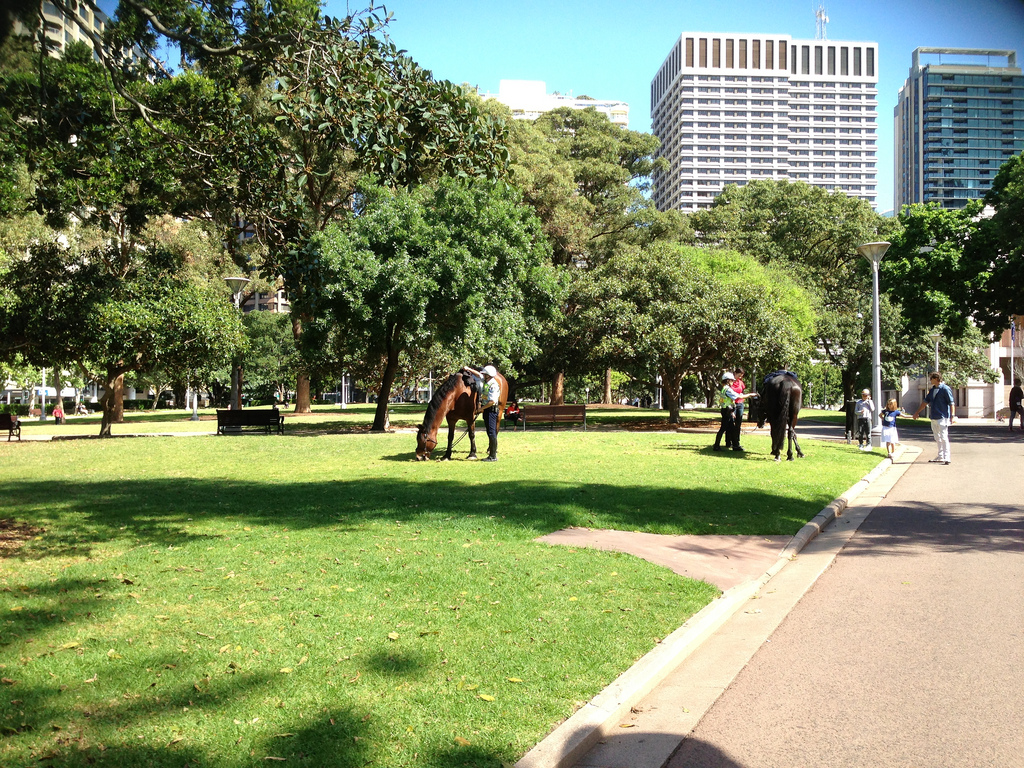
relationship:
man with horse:
[458, 361, 506, 459] [411, 371, 514, 461]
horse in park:
[411, 371, 514, 461] [2, 402, 907, 768]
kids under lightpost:
[851, 388, 900, 458] [852, 234, 895, 430]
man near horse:
[458, 361, 506, 459] [411, 371, 514, 461]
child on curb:
[874, 398, 901, 461] [519, 432, 911, 767]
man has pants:
[917, 366, 955, 465] [924, 413, 950, 462]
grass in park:
[0, 402, 896, 768] [2, 402, 907, 768]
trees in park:
[0, 0, 1022, 437] [2, 402, 907, 768]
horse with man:
[411, 371, 514, 461] [458, 361, 506, 459]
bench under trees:
[215, 402, 285, 436] [0, 0, 1022, 437]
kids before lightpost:
[851, 388, 900, 458] [852, 234, 895, 430]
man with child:
[917, 366, 955, 465] [874, 398, 901, 461]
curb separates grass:
[519, 432, 911, 767] [0, 402, 896, 768]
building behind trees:
[649, 30, 879, 421] [0, 0, 1022, 437]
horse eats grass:
[411, 371, 514, 461] [0, 402, 896, 768]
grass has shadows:
[0, 402, 896, 768] [2, 474, 1021, 564]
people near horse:
[705, 369, 757, 452] [753, 372, 806, 462]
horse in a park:
[758, 369, 805, 460] [0, 402, 1024, 768]